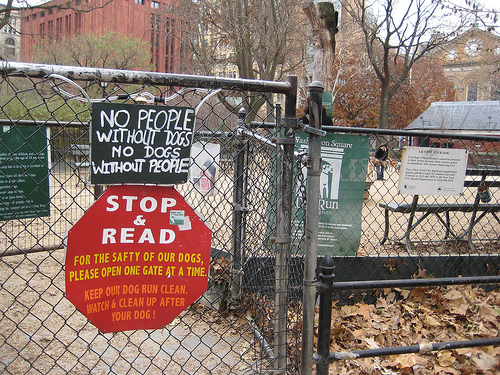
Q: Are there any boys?
A: No, there are no boys.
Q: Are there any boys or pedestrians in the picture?
A: No, there are no boys or pedestrians.